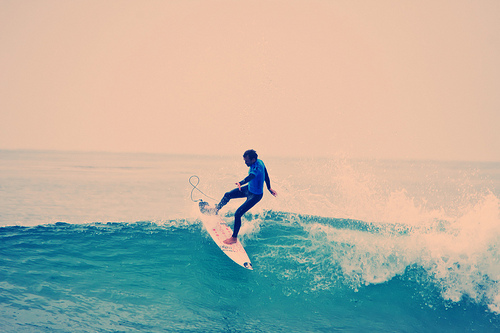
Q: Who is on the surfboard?
A: A person.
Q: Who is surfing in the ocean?
A: A man.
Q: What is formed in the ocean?
A: A wave.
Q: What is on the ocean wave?
A: Foam.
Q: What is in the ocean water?
A: Mist.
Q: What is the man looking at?
A: The ocean.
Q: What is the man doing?
A: Sea surfing.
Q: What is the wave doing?
A: Splashing.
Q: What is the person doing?
A: Surfing.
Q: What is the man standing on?
A: Surfboard.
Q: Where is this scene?
A: The ocean.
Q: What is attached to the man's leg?
A: Tether.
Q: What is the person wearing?
A: Wetsuit.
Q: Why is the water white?
A: Splashing.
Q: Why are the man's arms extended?
A: Balance.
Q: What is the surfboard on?
A: Wave.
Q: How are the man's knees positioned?
A: Bent.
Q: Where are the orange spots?
A: Middle of the board.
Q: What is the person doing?
A: Surfing.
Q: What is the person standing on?
A: Surfboard.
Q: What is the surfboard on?
A: Wave.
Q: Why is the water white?
A: Wave crashing.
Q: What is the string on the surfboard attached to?
A: The surfer's ankle.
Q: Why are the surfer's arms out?
A: Balance.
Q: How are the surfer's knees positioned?
A: Bent.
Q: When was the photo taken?
A: Day time.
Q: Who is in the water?
A: A man.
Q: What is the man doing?
A: Surfing.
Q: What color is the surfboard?
A: White.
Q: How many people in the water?
A: One.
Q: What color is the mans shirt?
A: Blue.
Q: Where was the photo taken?
A: The ocean.